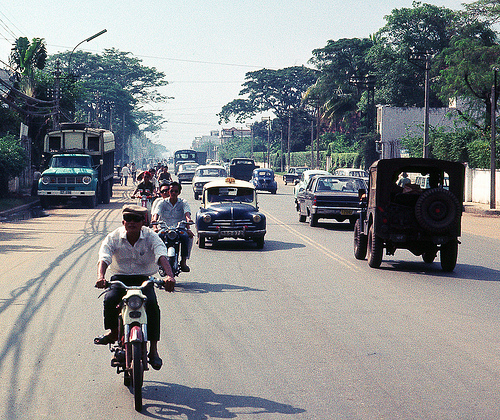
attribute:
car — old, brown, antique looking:
[351, 147, 466, 280]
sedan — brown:
[292, 135, 369, 248]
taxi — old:
[190, 173, 270, 253]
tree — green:
[12, 37, 40, 169]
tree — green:
[59, 50, 160, 124]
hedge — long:
[250, 141, 372, 184]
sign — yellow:
[220, 174, 240, 191]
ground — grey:
[224, 257, 394, 382]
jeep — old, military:
[360, 137, 481, 269]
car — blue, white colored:
[106, 126, 283, 247]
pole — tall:
[418, 49, 432, 156]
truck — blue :
[31, 132, 123, 207]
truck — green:
[31, 120, 119, 207]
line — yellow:
[257, 204, 367, 278]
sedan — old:
[295, 173, 369, 228]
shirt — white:
[90, 215, 174, 282]